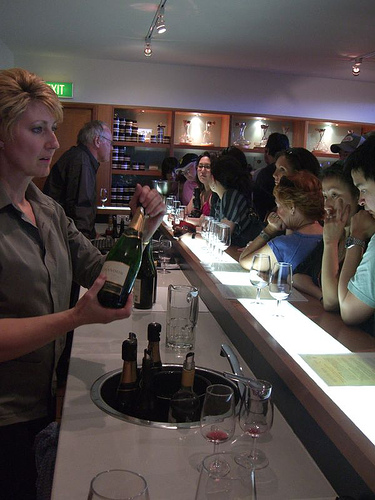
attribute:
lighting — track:
[138, 1, 175, 62]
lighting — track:
[339, 44, 373, 78]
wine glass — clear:
[234, 377, 274, 473]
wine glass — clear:
[195, 383, 237, 481]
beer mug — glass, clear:
[163, 283, 201, 356]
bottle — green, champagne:
[93, 197, 149, 307]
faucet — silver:
[216, 343, 259, 414]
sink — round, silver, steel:
[87, 354, 249, 432]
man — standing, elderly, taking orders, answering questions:
[43, 121, 116, 241]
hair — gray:
[73, 117, 112, 147]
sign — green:
[34, 75, 75, 100]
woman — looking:
[2, 66, 170, 499]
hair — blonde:
[2, 67, 64, 144]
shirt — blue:
[267, 227, 323, 275]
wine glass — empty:
[269, 263, 293, 327]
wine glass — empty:
[245, 250, 271, 310]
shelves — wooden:
[32, 101, 374, 242]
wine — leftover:
[201, 429, 230, 444]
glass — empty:
[213, 221, 231, 272]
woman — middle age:
[241, 175, 325, 290]